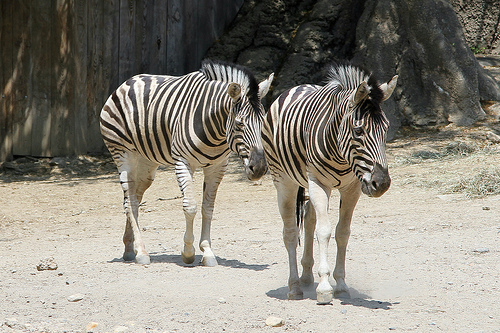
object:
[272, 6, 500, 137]
tree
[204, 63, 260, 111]
mane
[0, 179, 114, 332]
dirt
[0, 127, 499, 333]
ground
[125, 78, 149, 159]
stripes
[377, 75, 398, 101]
ear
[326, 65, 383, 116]
mane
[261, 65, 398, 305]
zebra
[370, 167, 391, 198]
nose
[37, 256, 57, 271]
rocks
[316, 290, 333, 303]
hooves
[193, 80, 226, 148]
stripes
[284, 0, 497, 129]
trunk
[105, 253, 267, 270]
shadow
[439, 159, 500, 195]
grass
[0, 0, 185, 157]
fence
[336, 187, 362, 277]
leg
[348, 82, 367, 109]
ear